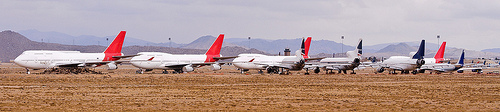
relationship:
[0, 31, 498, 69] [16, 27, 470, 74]
mountains behind airplanes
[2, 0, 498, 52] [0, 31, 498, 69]
sky over mountains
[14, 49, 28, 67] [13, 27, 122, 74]
nose of plane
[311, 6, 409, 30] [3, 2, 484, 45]
clouds in sky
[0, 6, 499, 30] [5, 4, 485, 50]
clouds in sky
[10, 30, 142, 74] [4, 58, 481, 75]
airplane on airstrip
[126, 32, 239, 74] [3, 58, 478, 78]
plane on airstrip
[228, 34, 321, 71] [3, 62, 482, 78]
plane on airstrip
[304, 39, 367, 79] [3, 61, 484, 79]
plane on airstrip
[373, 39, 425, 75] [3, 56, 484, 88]
airplane on airstrip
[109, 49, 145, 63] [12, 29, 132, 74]
wing of plane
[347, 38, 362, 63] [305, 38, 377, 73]
wing of plane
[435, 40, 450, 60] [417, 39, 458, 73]
wing of plane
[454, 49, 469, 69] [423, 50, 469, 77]
wing of plane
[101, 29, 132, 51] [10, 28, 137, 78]
tail of plane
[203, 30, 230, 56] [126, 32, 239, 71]
tail of plane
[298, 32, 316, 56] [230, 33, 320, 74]
tail of plane